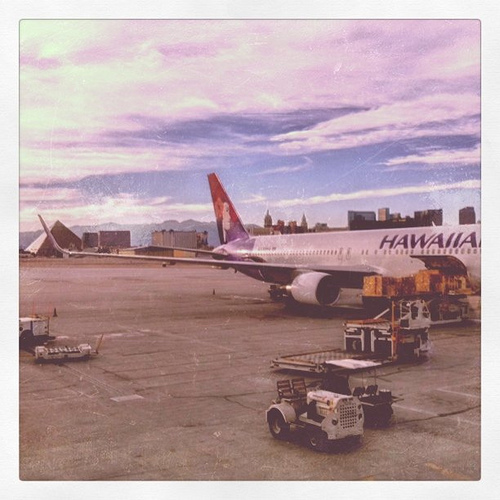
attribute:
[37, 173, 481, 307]
plane — grounded, parked, vehicle, large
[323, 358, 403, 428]
golf cart — parked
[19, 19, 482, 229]
sky — shining, purple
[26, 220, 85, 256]
pyramid — big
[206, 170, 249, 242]
tail — red, blue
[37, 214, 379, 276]
wing — long, bent, large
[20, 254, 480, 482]
tarmac — paved, grey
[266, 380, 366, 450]
truck — white